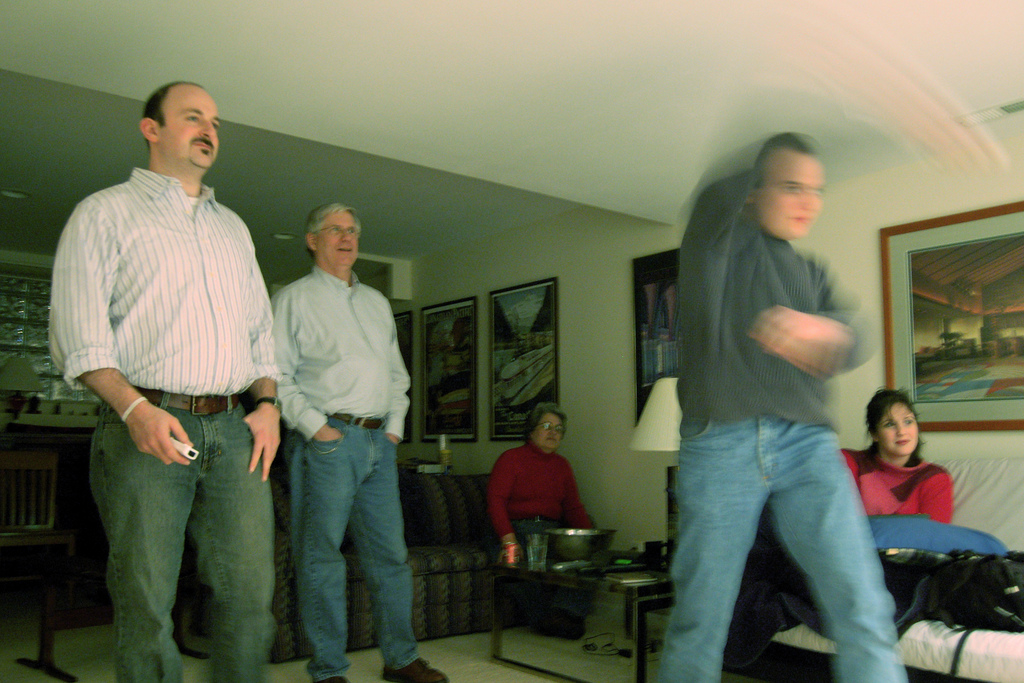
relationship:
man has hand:
[266, 195, 457, 679] [311, 423, 340, 443]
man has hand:
[266, 195, 457, 679] [380, 428, 400, 450]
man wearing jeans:
[266, 195, 457, 679] [282, 407, 427, 678]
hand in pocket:
[311, 423, 340, 443] [308, 417, 348, 446]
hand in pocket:
[380, 428, 400, 450] [373, 426, 404, 461]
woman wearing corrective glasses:
[501, 364, 579, 660] [493, 397, 610, 540]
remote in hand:
[168, 433, 199, 460] [132, 407, 204, 466]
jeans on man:
[300, 413, 424, 669] [270, 193, 437, 678]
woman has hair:
[843, 383, 965, 526] [856, 376, 911, 444]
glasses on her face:
[523, 417, 567, 435] [523, 410, 571, 469]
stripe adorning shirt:
[100, 188, 152, 383] [44, 160, 282, 400]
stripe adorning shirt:
[171, 178, 215, 390] [44, 160, 282, 400]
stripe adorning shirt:
[93, 348, 104, 368] [44, 160, 282, 400]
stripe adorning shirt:
[67, 221, 80, 356] [44, 160, 282, 400]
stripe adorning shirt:
[201, 208, 230, 397] [44, 160, 282, 400]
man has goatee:
[31, 58, 287, 681] [189, 128, 228, 165]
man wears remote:
[31, 58, 287, 681] [168, 435, 199, 460]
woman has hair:
[842, 367, 961, 515] [865, 380, 917, 413]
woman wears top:
[846, 378, 970, 521] [846, 447, 961, 512]